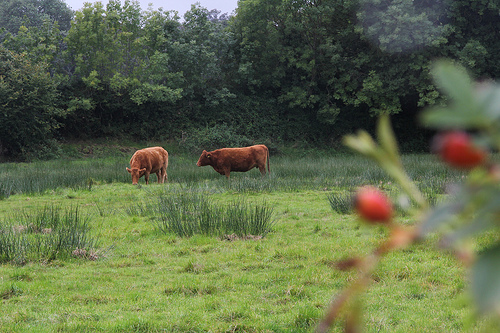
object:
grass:
[52, 213, 91, 260]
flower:
[357, 182, 392, 221]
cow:
[195, 143, 270, 176]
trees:
[69, 9, 145, 145]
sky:
[96, 0, 243, 13]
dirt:
[173, 261, 213, 276]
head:
[127, 167, 145, 182]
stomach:
[232, 157, 249, 170]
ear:
[124, 168, 131, 173]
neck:
[206, 151, 220, 163]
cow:
[127, 145, 169, 185]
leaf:
[422, 87, 436, 102]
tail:
[262, 146, 270, 173]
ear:
[141, 168, 148, 173]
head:
[194, 150, 214, 165]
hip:
[252, 148, 266, 163]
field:
[4, 184, 477, 330]